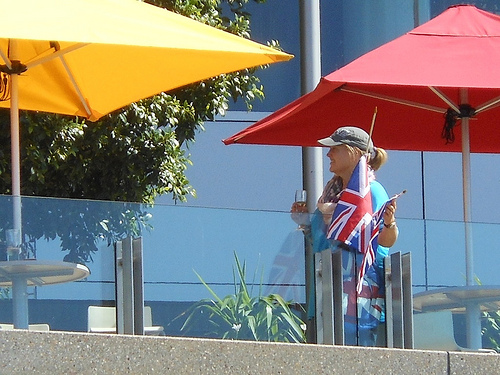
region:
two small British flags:
[311, 152, 408, 308]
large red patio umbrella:
[231, 0, 498, 141]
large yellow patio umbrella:
[4, 0, 301, 133]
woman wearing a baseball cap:
[286, 113, 403, 300]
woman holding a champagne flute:
[287, 126, 402, 288]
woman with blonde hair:
[288, 111, 428, 211]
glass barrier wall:
[17, 192, 300, 343]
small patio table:
[2, 233, 97, 299]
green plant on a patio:
[174, 258, 324, 350]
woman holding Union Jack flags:
[282, 121, 400, 284]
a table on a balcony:
[0, 239, 95, 300]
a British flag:
[321, 151, 387, 257]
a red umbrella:
[218, 5, 498, 147]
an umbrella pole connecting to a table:
[457, 97, 477, 284]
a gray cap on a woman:
[316, 116, 378, 153]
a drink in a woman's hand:
[289, 186, 314, 236]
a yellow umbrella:
[0, 0, 295, 117]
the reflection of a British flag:
[260, 228, 310, 298]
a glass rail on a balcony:
[1, 191, 499, 346]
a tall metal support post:
[296, 1, 334, 345]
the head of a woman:
[311, 120, 395, 182]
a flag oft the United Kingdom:
[321, 152, 379, 254]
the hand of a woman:
[379, 197, 404, 226]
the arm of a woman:
[373, 219, 401, 252]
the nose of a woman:
[323, 146, 335, 158]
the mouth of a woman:
[327, 155, 337, 166]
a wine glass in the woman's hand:
[285, 184, 315, 238]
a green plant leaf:
[188, 263, 230, 308]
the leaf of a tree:
[187, 185, 202, 201]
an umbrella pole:
[0, 65, 34, 336]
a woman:
[299, 49, 429, 371]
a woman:
[299, 114, 385, 346]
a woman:
[281, 100, 347, 315]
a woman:
[330, 100, 350, 296]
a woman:
[342, 120, 452, 311]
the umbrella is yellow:
[1, 2, 278, 129]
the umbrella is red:
[261, 1, 495, 164]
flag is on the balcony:
[315, 146, 395, 279]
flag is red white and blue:
[321, 151, 411, 280]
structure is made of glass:
[4, 184, 496, 329]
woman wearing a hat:
[309, 124, 403, 176]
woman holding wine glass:
[283, 191, 325, 242]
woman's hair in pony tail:
[353, 137, 400, 176]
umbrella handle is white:
[7, 67, 72, 301]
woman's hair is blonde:
[341, 142, 388, 171]